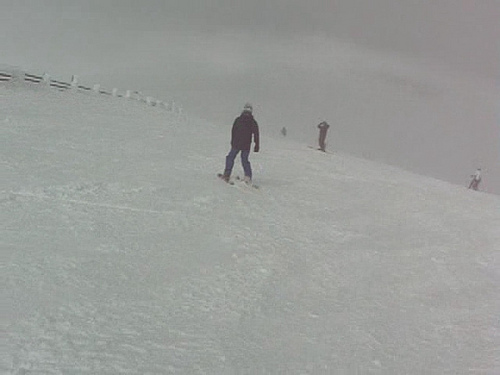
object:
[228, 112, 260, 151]
coat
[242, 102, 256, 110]
cap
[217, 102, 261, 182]
person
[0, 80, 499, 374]
slope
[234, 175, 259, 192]
skis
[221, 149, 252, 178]
jeans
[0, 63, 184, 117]
fence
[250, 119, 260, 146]
arms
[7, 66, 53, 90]
snow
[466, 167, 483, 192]
skier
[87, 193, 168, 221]
tracks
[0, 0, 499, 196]
sky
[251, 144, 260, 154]
gloves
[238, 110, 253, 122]
scarf